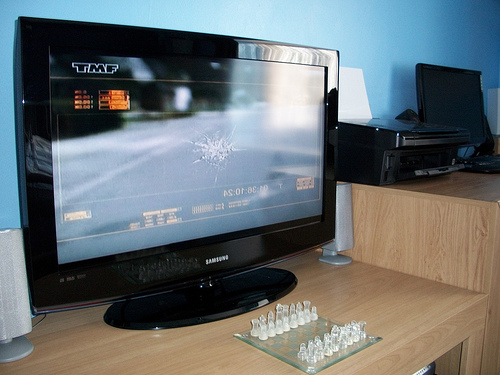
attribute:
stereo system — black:
[315, 114, 477, 197]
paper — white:
[339, 64, 374, 122]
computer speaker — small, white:
[2, 225, 38, 365]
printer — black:
[335, 120, 474, 185]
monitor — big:
[13, 14, 338, 331]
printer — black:
[337, 101, 492, 190]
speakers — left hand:
[2, 228, 39, 363]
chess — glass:
[230, 303, 385, 373]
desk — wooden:
[333, 166, 498, 373]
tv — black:
[13, 15, 340, 274]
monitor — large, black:
[19, 5, 351, 302]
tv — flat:
[5, 7, 367, 309]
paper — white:
[336, 59, 372, 122]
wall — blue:
[0, 0, 497, 255]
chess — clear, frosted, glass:
[229, 275, 389, 373]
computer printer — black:
[336, 64, 471, 181]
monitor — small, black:
[413, 59, 499, 141]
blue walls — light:
[309, 7, 429, 107]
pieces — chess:
[248, 297, 318, 339]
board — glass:
[231, 315, 382, 373]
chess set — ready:
[233, 299, 385, 372]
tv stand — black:
[95, 264, 302, 335]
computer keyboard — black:
[462, 152, 499, 177]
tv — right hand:
[46, 50, 351, 253]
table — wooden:
[0, 287, 483, 374]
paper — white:
[330, 64, 388, 140]